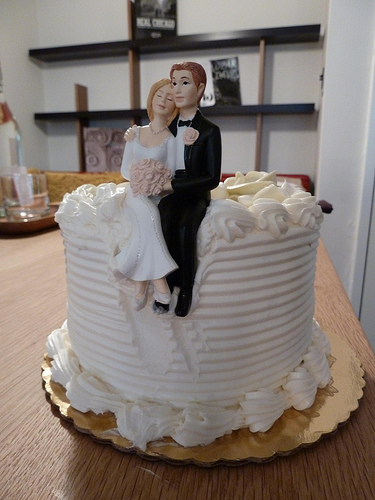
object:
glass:
[0, 160, 51, 218]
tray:
[0, 213, 70, 242]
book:
[209, 55, 244, 108]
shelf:
[29, 4, 321, 123]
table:
[1, 239, 47, 484]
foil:
[140, 422, 344, 466]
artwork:
[194, 193, 290, 243]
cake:
[43, 166, 334, 455]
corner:
[308, 0, 337, 25]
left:
[0, 0, 80, 124]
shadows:
[77, 372, 313, 499]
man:
[152, 62, 224, 319]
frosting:
[61, 321, 362, 466]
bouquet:
[130, 154, 174, 199]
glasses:
[0, 165, 49, 223]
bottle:
[7, 138, 32, 206]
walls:
[1, 2, 130, 112]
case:
[29, 45, 130, 112]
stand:
[235, 406, 358, 441]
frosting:
[67, 211, 244, 359]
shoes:
[130, 266, 156, 312]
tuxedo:
[158, 113, 220, 288]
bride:
[110, 78, 179, 310]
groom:
[153, 62, 223, 315]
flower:
[181, 124, 201, 147]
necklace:
[146, 120, 169, 136]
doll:
[112, 61, 221, 317]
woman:
[108, 78, 180, 310]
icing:
[188, 207, 285, 387]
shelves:
[28, 22, 318, 67]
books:
[134, 0, 180, 40]